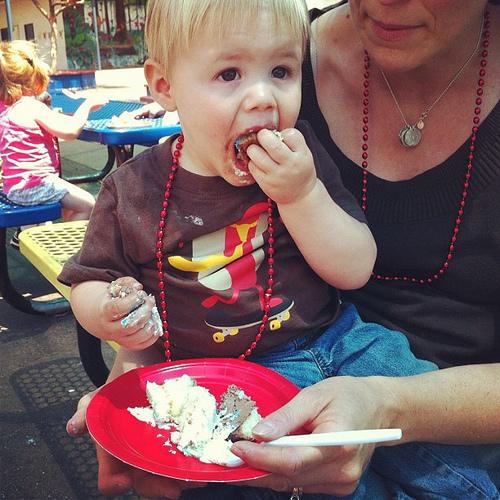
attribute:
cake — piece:
[123, 358, 290, 474]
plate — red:
[77, 332, 352, 492]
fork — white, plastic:
[186, 407, 458, 474]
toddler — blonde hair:
[119, 2, 497, 487]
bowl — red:
[84, 356, 308, 483]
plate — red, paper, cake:
[32, 327, 289, 497]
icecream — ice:
[127, 368, 284, 467]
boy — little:
[104, 12, 365, 357]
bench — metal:
[3, 197, 62, 217]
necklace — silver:
[374, 25, 491, 162]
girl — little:
[0, 31, 110, 220]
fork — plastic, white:
[258, 420, 412, 453]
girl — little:
[1, 39, 106, 246]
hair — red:
[1, 39, 49, 105]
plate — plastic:
[85, 358, 309, 480]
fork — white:
[221, 428, 400, 465]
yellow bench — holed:
[13, 202, 62, 281]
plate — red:
[78, 342, 493, 401]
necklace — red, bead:
[338, 57, 484, 302]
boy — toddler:
[147, 0, 328, 278]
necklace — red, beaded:
[146, 123, 295, 374]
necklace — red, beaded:
[337, 11, 495, 296]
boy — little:
[55, 2, 496, 499]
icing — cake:
[164, 409, 244, 465]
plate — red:
[125, 310, 292, 450]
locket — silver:
[393, 108, 426, 155]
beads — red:
[357, 1, 492, 283]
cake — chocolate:
[146, 366, 263, 457]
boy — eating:
[55, 2, 429, 382]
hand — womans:
[224, 374, 401, 498]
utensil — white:
[205, 422, 399, 449]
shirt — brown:
[77, 123, 370, 369]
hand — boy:
[239, 122, 318, 205]